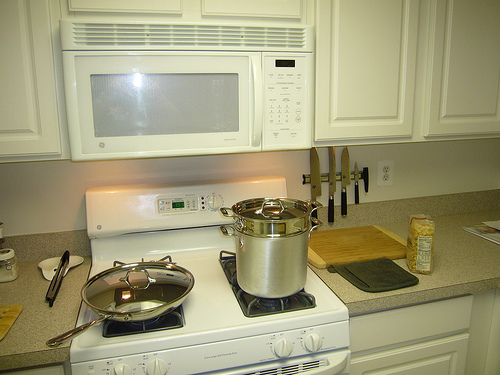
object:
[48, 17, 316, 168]
microwave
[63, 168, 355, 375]
stove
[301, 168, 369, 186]
knife holder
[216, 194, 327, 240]
pot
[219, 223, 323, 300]
pot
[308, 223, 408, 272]
chopping board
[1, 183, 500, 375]
counter top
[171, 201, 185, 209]
clock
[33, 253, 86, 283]
spoon rest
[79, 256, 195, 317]
lid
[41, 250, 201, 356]
pan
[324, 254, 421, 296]
hot pad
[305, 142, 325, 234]
knives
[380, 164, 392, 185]
electrical outlet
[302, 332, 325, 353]
knob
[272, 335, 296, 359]
knob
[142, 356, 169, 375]
knob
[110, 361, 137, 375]
knob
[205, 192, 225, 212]
knob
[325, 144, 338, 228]
knife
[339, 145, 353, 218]
knife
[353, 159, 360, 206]
knife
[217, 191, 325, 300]
double boiler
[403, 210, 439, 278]
bag of pasta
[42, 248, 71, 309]
tongs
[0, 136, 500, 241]
wall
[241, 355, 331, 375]
vent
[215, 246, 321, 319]
burner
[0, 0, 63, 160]
door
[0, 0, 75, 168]
cabinet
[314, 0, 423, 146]
door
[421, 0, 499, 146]
door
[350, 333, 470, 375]
door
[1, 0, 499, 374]
kitchen